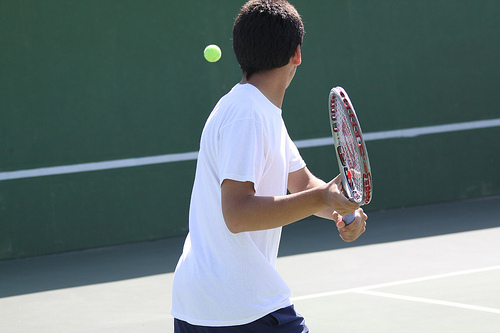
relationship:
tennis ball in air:
[201, 40, 226, 64] [8, 8, 498, 325]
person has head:
[166, 4, 377, 332] [228, 0, 310, 81]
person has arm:
[166, 4, 377, 332] [222, 101, 329, 243]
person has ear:
[166, 4, 377, 332] [294, 41, 307, 70]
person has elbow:
[166, 4, 377, 332] [225, 192, 255, 238]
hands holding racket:
[326, 168, 367, 241] [327, 83, 374, 228]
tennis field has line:
[3, 184, 500, 327] [2, 109, 500, 184]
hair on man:
[230, 0, 311, 72] [166, 0, 370, 331]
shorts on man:
[169, 305, 314, 330] [166, 0, 370, 331]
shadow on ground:
[4, 194, 500, 299] [3, 195, 499, 332]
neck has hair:
[235, 64, 264, 89] [239, 72, 252, 88]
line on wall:
[2, 109, 500, 184] [5, 0, 499, 253]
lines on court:
[133, 254, 500, 330] [2, 197, 499, 324]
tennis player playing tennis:
[167, 4, 371, 331] [4, 4, 499, 327]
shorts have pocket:
[169, 305, 314, 330] [172, 307, 306, 330]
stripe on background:
[1, 115, 500, 192] [5, 5, 499, 253]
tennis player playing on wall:
[167, 4, 371, 331] [5, 0, 499, 253]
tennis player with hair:
[167, 4, 371, 331] [230, 0, 311, 72]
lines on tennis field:
[133, 254, 500, 330] [3, 184, 500, 327]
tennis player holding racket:
[167, 4, 371, 331] [327, 83, 374, 228]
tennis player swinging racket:
[167, 4, 371, 331] [327, 83, 374, 228]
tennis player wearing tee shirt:
[167, 4, 371, 331] [169, 78, 316, 328]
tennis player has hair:
[167, 4, 371, 331] [230, 0, 311, 72]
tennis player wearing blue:
[167, 4, 371, 331] [174, 308, 317, 332]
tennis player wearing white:
[167, 4, 371, 331] [169, 85, 315, 328]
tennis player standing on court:
[167, 4, 371, 331] [2, 197, 499, 324]